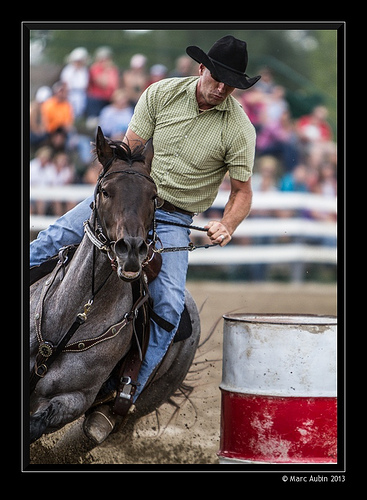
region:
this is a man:
[154, 38, 252, 241]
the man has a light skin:
[233, 199, 242, 217]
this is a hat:
[205, 36, 239, 77]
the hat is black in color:
[223, 46, 239, 61]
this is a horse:
[93, 158, 145, 338]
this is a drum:
[223, 323, 310, 447]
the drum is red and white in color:
[257, 366, 298, 448]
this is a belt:
[157, 200, 172, 212]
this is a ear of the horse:
[93, 124, 107, 163]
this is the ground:
[139, 428, 201, 463]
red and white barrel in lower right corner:
[212, 304, 339, 464]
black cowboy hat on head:
[183, 33, 256, 111]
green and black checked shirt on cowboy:
[134, 76, 252, 212]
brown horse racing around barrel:
[34, 123, 209, 437]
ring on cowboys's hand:
[200, 222, 244, 248]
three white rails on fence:
[16, 191, 332, 277]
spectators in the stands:
[33, 41, 319, 191]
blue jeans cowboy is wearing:
[32, 197, 201, 385]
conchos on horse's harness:
[30, 251, 151, 380]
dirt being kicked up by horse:
[75, 417, 216, 468]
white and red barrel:
[217, 311, 337, 463]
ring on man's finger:
[218, 233, 226, 241]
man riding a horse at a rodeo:
[28, 35, 255, 463]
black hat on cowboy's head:
[185, 34, 261, 89]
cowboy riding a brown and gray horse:
[30, 34, 257, 462]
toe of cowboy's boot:
[82, 404, 115, 441]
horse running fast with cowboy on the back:
[29, 35, 256, 466]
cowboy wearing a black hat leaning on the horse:
[29, 34, 261, 464]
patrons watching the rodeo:
[30, 46, 89, 183]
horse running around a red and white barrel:
[29, 125, 219, 464]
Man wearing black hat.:
[189, 31, 278, 93]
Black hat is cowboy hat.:
[194, 46, 266, 92]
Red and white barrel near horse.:
[215, 366, 319, 486]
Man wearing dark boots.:
[84, 402, 141, 462]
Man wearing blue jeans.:
[148, 249, 203, 401]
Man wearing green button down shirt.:
[160, 94, 230, 210]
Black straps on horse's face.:
[99, 175, 170, 319]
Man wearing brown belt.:
[158, 195, 203, 220]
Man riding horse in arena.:
[95, 132, 192, 362]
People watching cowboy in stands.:
[56, 67, 328, 157]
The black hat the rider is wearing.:
[183, 33, 262, 89]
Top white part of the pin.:
[221, 310, 343, 399]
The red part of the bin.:
[221, 390, 341, 459]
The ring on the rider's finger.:
[220, 232, 224, 239]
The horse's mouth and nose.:
[111, 232, 152, 286]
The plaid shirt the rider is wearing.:
[132, 70, 253, 220]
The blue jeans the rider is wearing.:
[38, 178, 207, 398]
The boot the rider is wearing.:
[95, 381, 121, 451]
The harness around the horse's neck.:
[41, 230, 131, 378]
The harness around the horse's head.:
[89, 160, 171, 280]